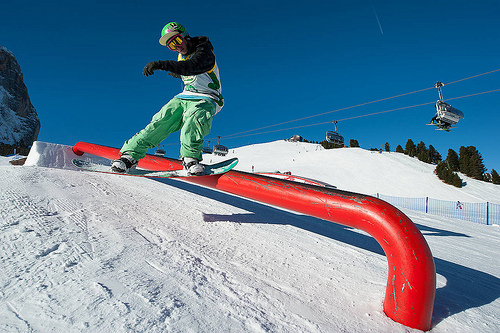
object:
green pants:
[118, 95, 220, 162]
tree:
[382, 140, 391, 154]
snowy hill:
[0, 138, 499, 333]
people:
[425, 104, 442, 126]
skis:
[425, 123, 438, 126]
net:
[367, 192, 499, 226]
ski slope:
[0, 147, 499, 332]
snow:
[0, 136, 499, 333]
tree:
[346, 136, 362, 148]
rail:
[71, 140, 438, 332]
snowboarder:
[109, 20, 226, 177]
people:
[426, 106, 456, 133]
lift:
[433, 79, 464, 125]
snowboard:
[69, 157, 238, 180]